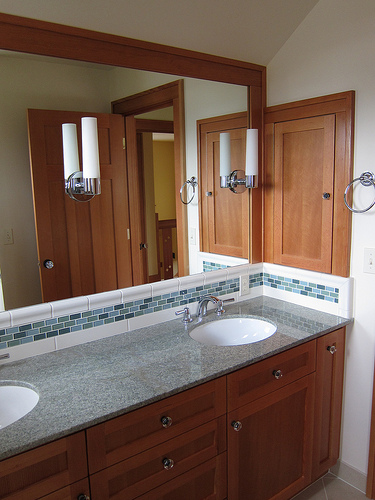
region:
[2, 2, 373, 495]
Double sinks in a bathroom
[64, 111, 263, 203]
Two wall sconces mounted on a mirror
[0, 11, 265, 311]
A large frame mirror mounted on a wall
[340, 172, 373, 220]
A towel ring mounted on a wall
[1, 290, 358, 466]
Grey marble countertop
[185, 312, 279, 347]
A white undermount sink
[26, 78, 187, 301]
The reflection of an open door and doorway in the mirror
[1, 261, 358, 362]
Tiled backsplash above the sink counter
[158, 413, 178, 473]
Two glass knobs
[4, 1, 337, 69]
A slanted ceiling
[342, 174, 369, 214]
towel ring hanging from wall in bathroom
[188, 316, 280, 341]
sink in marble bathroom counter top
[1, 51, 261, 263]
mirror in bathroom over sink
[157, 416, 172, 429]
knob on dresser under sink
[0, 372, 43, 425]
one of two sinks in marble bathroom top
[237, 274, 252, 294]
electric outlet in bathroom sink area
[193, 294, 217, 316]
water faucet of bathroom sink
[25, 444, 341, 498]
bathroom sink cabinet area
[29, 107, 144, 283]
reflection of bathroom door in the mirror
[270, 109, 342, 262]
towel cabinet on the wall in bathroom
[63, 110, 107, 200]
a light connected to a mirror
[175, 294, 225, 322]
a faucet next to the sink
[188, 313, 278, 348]
the sink next to the faucet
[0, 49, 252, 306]
the mirror on the wall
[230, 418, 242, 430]
a knob on the door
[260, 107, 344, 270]
a cabinet with a door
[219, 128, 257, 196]
another light on the mirror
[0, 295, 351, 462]
the grey countertop where the sinks are at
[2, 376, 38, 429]
the other sink in the bathroom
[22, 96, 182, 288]
the open door reflected in the mirror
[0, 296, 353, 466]
a marble grey vanity top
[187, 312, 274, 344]
white recessed bathroom sink basin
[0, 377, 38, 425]
white recessed bathroom sink basin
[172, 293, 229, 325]
chrome bathroom faucet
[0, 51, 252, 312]
a bathroom wall mounted vanity mirror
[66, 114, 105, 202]
a vanity mirror light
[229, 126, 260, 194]
a vanity mirror light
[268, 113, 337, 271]
a brown cabinet door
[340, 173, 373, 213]
a chrome towel hanger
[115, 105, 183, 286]
reflection of an open bathroom door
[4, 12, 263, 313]
a mirror in a bathroom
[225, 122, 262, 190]
a lamp on right side of mirror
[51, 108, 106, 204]
a lamp on center of mirror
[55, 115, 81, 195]
reflection of a light on a mirror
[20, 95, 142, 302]
the door of the bathroom is reflected on the mirror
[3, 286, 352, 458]
two sinks on counter of bathroom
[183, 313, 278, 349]
sinks is white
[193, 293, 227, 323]
faucet is color silver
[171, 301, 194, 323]
handle of faucet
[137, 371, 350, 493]
cabinets under the faucet